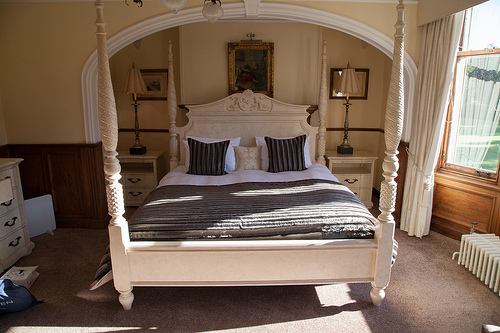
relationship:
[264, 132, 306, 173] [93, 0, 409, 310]
pillow on bed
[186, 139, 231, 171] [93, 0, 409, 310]
pillow on bed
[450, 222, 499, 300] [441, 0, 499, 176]
heater by window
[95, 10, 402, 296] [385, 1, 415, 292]
bed has posts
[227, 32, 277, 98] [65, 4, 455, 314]
framed picture behind bed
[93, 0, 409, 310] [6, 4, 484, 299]
bed in bedroom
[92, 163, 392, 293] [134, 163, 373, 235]
comforter covering mattress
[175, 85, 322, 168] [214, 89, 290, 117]
headboard with design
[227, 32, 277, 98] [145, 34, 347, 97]
framed picture on wall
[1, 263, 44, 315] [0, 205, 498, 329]
clutter on floor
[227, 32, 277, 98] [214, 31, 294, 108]
framed picture in frame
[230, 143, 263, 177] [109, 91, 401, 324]
pillow on bed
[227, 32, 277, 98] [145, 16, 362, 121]
framed picture on wall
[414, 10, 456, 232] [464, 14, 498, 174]
drapes on window